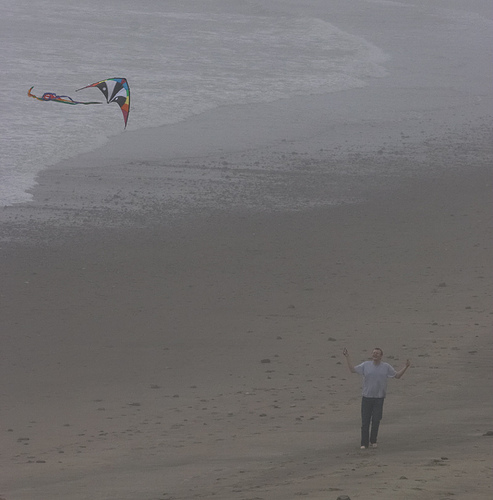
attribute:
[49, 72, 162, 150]
kite — flying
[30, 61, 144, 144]
kite — airborne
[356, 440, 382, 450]
shoes — white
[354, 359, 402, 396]
shirt — white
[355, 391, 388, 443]
pants — gray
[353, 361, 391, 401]
shirt — white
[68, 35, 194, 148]
kite — face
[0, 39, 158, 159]
kite — colorful, airborne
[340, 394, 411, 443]
pants — black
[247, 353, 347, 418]
sand — disturbed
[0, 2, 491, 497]
beach — SANDY, grey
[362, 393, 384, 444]
pants — dark colored